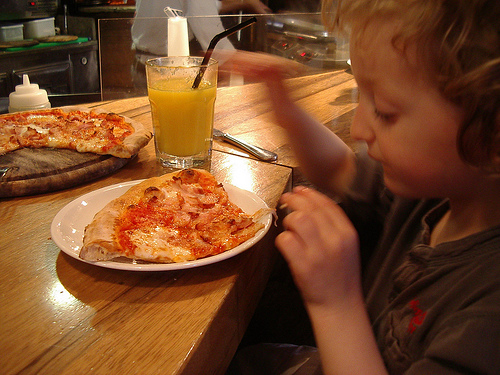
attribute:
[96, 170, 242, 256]
pizza — sliced, large, piece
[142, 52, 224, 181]
glass — juice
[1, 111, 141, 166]
pizza — pie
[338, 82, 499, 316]
kid — eating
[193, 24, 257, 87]
straw — black, plastic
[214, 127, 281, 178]
knife — metal, shiny, silver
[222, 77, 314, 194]
table — wooden, smooth, brown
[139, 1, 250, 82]
man — cooking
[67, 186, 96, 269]
plate — beautiful, white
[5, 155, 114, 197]
cutting board — grey, wooden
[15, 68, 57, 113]
bottle — white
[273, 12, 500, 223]
boy — sitting, little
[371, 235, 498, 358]
shirt — brown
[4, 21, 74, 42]
bins — plastic, white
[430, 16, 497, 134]
hair — long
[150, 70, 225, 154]
drink — orange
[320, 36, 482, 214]
girl — brown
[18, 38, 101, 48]
counter — green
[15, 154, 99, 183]
slice — missing